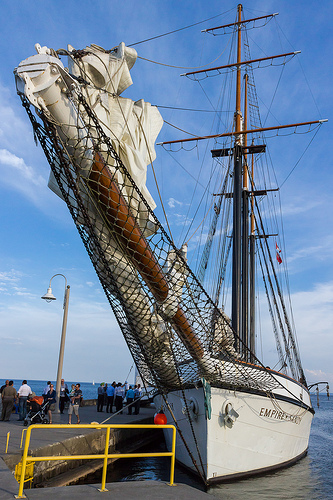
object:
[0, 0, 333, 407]
sky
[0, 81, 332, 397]
clouds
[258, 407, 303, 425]
lettering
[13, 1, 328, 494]
boat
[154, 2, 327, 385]
sail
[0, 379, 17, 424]
people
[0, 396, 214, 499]
pier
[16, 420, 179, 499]
rail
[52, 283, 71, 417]
post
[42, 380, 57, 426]
people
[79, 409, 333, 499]
ripples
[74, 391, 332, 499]
water